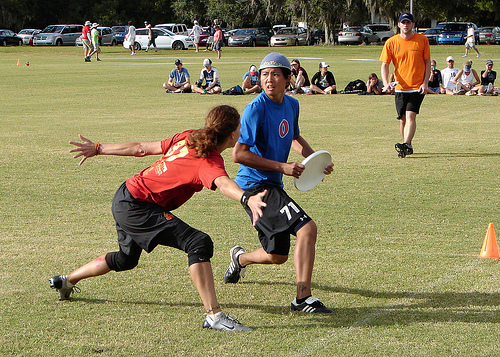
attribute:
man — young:
[223, 52, 333, 313]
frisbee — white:
[295, 151, 333, 192]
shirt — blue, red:
[235, 89, 299, 191]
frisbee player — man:
[224, 53, 334, 311]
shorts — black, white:
[242, 184, 311, 255]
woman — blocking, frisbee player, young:
[48, 104, 267, 332]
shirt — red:
[125, 130, 228, 211]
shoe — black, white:
[291, 297, 334, 314]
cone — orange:
[479, 223, 499, 259]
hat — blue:
[260, 53, 293, 70]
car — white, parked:
[123, 27, 194, 50]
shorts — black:
[111, 181, 182, 255]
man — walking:
[379, 12, 431, 156]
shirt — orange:
[378, 33, 430, 91]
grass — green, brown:
[0, 43, 499, 356]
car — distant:
[270, 27, 311, 46]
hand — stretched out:
[244, 189, 268, 227]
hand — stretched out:
[70, 134, 95, 166]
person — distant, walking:
[85, 21, 107, 61]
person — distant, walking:
[80, 20, 95, 60]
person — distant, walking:
[124, 22, 137, 57]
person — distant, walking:
[142, 20, 159, 51]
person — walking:
[186, 20, 207, 53]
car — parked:
[436, 22, 479, 46]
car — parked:
[364, 24, 394, 43]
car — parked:
[154, 23, 189, 37]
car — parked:
[111, 26, 127, 43]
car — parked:
[1, 29, 25, 47]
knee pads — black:
[106, 223, 214, 272]